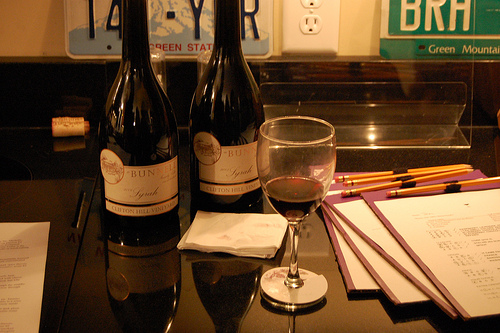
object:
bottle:
[96, 1, 178, 224]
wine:
[263, 175, 328, 216]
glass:
[255, 116, 337, 307]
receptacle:
[282, 0, 340, 58]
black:
[0, 236, 29, 332]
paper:
[0, 221, 52, 332]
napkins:
[175, 209, 289, 261]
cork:
[48, 114, 92, 140]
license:
[380, 2, 499, 62]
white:
[399, 1, 472, 33]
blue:
[73, 36, 107, 53]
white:
[61, 2, 89, 26]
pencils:
[387, 177, 499, 197]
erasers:
[335, 191, 351, 198]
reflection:
[99, 214, 184, 332]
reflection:
[190, 259, 263, 332]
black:
[50, 249, 332, 332]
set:
[357, 177, 498, 321]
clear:
[284, 221, 301, 283]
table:
[292, 121, 499, 332]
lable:
[99, 147, 179, 218]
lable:
[192, 130, 275, 197]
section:
[66, 1, 112, 60]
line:
[104, 191, 179, 208]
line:
[198, 175, 258, 187]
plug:
[298, 17, 323, 37]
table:
[0, 170, 97, 333]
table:
[53, 268, 257, 332]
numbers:
[84, 3, 123, 39]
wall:
[340, 2, 381, 59]